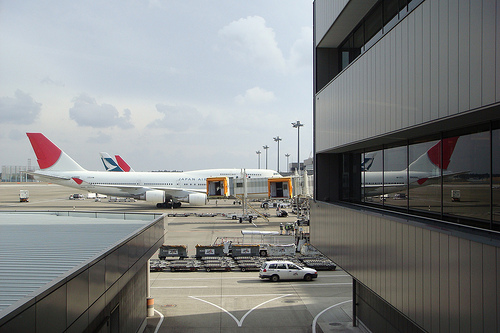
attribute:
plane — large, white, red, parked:
[24, 132, 283, 208]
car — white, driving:
[257, 259, 318, 282]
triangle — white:
[186, 292, 291, 325]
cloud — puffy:
[68, 91, 133, 132]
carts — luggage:
[156, 239, 325, 259]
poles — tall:
[255, 121, 305, 177]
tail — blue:
[98, 149, 123, 173]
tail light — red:
[260, 269, 266, 271]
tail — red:
[115, 153, 135, 171]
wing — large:
[96, 183, 210, 205]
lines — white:
[148, 273, 354, 290]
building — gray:
[0, 211, 165, 331]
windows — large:
[315, 0, 430, 95]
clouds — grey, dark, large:
[0, 87, 136, 130]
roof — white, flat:
[0, 210, 167, 320]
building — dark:
[312, 0, 499, 333]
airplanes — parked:
[96, 150, 138, 173]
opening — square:
[206, 176, 229, 198]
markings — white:
[150, 275, 354, 332]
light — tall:
[291, 119, 305, 173]